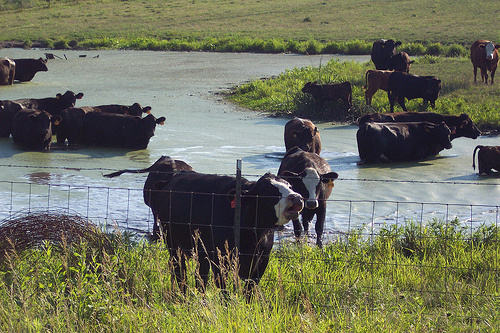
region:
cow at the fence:
[127, 156, 311, 295]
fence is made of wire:
[321, 203, 480, 320]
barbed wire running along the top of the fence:
[326, 170, 453, 192]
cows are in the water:
[6, 85, 166, 153]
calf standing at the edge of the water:
[304, 73, 359, 110]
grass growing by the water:
[304, 236, 471, 316]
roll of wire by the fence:
[5, 219, 75, 306]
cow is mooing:
[254, 178, 302, 223]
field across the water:
[119, 13, 276, 67]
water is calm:
[144, 58, 181, 92]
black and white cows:
[103, 147, 358, 319]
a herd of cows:
[3, 25, 498, 308]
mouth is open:
[283, 201, 297, 213]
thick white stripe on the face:
[301, 168, 323, 212]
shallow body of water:
[3, 38, 496, 258]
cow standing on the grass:
[148, 160, 298, 289]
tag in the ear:
[230, 193, 237, 212]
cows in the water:
[2, 45, 176, 188]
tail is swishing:
[98, 159, 154, 183]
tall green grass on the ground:
[2, 223, 498, 330]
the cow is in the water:
[392, 134, 419, 171]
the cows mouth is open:
[276, 193, 305, 222]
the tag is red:
[226, 193, 239, 211]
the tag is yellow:
[324, 177, 336, 190]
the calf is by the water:
[299, 77, 337, 126]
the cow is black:
[388, 130, 415, 147]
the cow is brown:
[473, 46, 483, 63]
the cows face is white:
[302, 172, 321, 195]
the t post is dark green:
[231, 189, 243, 233]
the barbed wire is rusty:
[23, 215, 44, 235]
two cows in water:
[93, 103, 388, 307]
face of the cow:
[243, 157, 321, 254]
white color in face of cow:
[275, 174, 312, 207]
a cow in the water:
[294, 139, 349, 269]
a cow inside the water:
[281, 115, 348, 157]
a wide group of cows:
[0, 53, 489, 298]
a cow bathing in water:
[344, 100, 491, 185]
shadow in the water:
[332, 142, 358, 190]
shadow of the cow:
[333, 137, 364, 196]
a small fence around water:
[31, 186, 497, 261]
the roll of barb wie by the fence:
[1, 195, 107, 276]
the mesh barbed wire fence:
[353, 168, 499, 332]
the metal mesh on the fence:
[321, 198, 494, 331]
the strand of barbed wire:
[235, 166, 496, 190]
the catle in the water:
[352, 103, 482, 175]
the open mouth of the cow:
[279, 190, 309, 222]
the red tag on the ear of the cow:
[227, 195, 237, 208]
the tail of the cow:
[100, 153, 145, 198]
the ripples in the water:
[351, 208, 493, 236]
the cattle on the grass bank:
[355, 34, 448, 112]